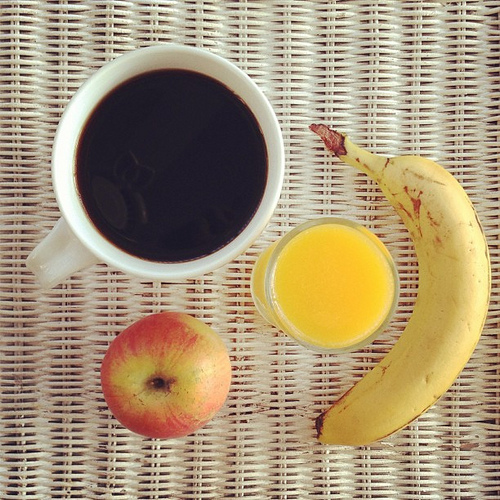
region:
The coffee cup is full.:
[16, 39, 293, 311]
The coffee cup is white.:
[18, 33, 291, 315]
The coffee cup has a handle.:
[24, 33, 291, 313]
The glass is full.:
[240, 194, 408, 357]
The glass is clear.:
[248, 208, 415, 367]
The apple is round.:
[78, 308, 246, 455]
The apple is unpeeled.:
[81, 302, 247, 454]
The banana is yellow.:
[298, 103, 497, 466]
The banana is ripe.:
[296, 106, 496, 459]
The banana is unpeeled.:
[301, 99, 497, 472]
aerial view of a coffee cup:
[27, 42, 284, 290]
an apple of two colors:
[100, 310, 232, 440]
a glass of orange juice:
[250, 215, 397, 351]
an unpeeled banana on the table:
[308, 123, 492, 448]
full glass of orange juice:
[249, 215, 401, 350]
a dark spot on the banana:
[373, 398, 441, 445]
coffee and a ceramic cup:
[25, 43, 283, 290]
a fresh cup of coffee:
[26, 45, 285, 287]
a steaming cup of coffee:
[25, 43, 285, 293]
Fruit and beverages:
[21, 42, 481, 481]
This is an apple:
[90, 298, 244, 442]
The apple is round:
[84, 313, 244, 435]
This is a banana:
[304, 114, 487, 464]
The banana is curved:
[313, 105, 498, 452]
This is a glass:
[258, 213, 402, 363]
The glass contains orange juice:
[251, 212, 398, 366]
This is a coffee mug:
[1, 56, 297, 283]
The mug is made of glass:
[25, 43, 280, 299]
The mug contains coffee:
[7, 50, 294, 290]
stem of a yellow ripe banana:
[315, 122, 390, 182]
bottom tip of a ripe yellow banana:
[313, 409, 329, 446]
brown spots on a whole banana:
[384, 180, 433, 241]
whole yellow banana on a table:
[309, 122, 496, 447]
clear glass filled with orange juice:
[249, 217, 402, 353]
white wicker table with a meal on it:
[0, 2, 496, 494]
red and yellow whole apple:
[98, 308, 233, 434]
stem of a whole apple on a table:
[143, 370, 171, 397]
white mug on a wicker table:
[28, 43, 283, 290]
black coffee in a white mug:
[74, 63, 268, 265]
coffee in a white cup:
[16, 37, 296, 290]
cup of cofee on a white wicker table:
[28, 44, 298, 295]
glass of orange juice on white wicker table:
[245, 207, 409, 372]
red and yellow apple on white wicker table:
[78, 288, 268, 449]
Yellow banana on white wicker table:
[304, 116, 498, 463]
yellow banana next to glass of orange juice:
[242, 117, 496, 460]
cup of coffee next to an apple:
[26, 38, 296, 448]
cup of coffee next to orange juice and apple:
[18, 37, 414, 449]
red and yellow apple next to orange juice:
[95, 216, 413, 454]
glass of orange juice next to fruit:
[96, 212, 496, 467]